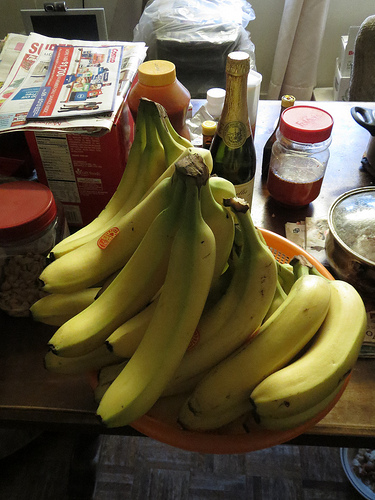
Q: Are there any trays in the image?
A: No, there are no trays.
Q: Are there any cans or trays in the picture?
A: No, there are no trays or cans.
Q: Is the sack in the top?
A: Yes, the sack is in the top of the image.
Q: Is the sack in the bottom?
A: No, the sack is in the top of the image.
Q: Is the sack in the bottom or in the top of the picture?
A: The sack is in the top of the image.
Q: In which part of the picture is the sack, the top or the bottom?
A: The sack is in the top of the image.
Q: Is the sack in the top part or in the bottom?
A: The sack is in the top of the image.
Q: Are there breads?
A: No, there are no breads.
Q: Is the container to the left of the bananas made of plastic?
A: Yes, the container is made of plastic.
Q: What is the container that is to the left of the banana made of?
A: The container is made of plastic.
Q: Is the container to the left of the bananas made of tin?
A: No, the container is made of plastic.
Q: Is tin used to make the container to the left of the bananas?
A: No, the container is made of plastic.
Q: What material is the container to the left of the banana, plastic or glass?
A: The container is made of plastic.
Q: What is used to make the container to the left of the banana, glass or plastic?
A: The container is made of plastic.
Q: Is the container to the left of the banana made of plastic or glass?
A: The container is made of plastic.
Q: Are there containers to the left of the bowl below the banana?
A: Yes, there is a container to the left of the bowl.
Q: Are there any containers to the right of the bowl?
A: No, the container is to the left of the bowl.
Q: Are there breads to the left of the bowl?
A: No, there is a container to the left of the bowl.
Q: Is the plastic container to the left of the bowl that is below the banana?
A: Yes, the container is to the left of the bowl.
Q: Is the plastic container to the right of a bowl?
A: No, the container is to the left of a bowl.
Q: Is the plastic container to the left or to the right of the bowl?
A: The container is to the left of the bowl.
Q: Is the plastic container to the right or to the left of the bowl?
A: The container is to the left of the bowl.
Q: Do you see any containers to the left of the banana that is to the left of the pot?
A: Yes, there is a container to the left of the banana.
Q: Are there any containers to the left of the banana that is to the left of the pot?
A: Yes, there is a container to the left of the banana.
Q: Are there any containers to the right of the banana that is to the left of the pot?
A: No, the container is to the left of the banana.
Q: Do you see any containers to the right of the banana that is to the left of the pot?
A: No, the container is to the left of the banana.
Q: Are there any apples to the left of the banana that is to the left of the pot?
A: No, there is a container to the left of the banana.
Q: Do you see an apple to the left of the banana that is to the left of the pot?
A: No, there is a container to the left of the banana.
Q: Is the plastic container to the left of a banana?
A: Yes, the container is to the left of a banana.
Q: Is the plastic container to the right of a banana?
A: No, the container is to the left of a banana.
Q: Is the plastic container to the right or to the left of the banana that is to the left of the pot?
A: The container is to the left of the banana.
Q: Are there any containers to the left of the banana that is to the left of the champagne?
A: Yes, there is a container to the left of the banana.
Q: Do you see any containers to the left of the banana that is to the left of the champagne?
A: Yes, there is a container to the left of the banana.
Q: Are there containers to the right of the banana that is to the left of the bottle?
A: No, the container is to the left of the banana.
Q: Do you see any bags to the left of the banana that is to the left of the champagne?
A: No, there is a container to the left of the banana.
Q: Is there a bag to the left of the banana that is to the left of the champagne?
A: No, there is a container to the left of the banana.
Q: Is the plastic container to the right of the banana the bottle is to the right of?
A: No, the container is to the left of the banana.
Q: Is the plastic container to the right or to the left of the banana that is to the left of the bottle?
A: The container is to the left of the banana.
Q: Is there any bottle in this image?
A: Yes, there is a bottle.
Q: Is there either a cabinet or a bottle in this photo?
A: Yes, there is a bottle.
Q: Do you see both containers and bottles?
A: Yes, there are both a bottle and a container.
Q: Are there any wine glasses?
A: No, there are no wine glasses.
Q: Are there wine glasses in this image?
A: No, there are no wine glasses.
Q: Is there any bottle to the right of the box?
A: Yes, there is a bottle to the right of the box.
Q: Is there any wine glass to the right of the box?
A: No, there is a bottle to the right of the box.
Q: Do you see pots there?
A: Yes, there is a pot.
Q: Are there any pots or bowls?
A: Yes, there is a pot.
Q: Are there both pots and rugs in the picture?
A: No, there is a pot but no rugs.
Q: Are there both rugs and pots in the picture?
A: No, there is a pot but no rugs.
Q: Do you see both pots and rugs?
A: No, there is a pot but no rugs.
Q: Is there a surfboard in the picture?
A: No, there are no surfboards.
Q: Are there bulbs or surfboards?
A: No, there are no surfboards or bulbs.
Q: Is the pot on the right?
A: Yes, the pot is on the right of the image.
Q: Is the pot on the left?
A: No, the pot is on the right of the image.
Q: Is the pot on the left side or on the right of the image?
A: The pot is on the right of the image.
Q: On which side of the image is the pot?
A: The pot is on the right of the image.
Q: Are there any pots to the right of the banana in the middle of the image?
A: Yes, there is a pot to the right of the banana.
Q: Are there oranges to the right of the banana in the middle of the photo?
A: No, there is a pot to the right of the banana.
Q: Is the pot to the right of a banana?
A: Yes, the pot is to the right of a banana.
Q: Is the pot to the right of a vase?
A: No, the pot is to the right of a banana.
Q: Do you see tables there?
A: Yes, there is a table.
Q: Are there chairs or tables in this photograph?
A: Yes, there is a table.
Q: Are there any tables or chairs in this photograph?
A: Yes, there is a table.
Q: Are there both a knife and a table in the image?
A: No, there is a table but no knives.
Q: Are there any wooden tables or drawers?
A: Yes, there is a wood table.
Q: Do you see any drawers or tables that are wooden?
A: Yes, the table is wooden.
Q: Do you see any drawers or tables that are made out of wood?
A: Yes, the table is made of wood.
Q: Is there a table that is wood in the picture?
A: Yes, there is a wood table.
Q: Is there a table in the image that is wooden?
A: Yes, there is a table that is wooden.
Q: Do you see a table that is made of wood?
A: Yes, there is a table that is made of wood.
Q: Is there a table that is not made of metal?
A: Yes, there is a table that is made of wood.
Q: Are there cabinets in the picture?
A: No, there are no cabinets.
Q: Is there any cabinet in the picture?
A: No, there are no cabinets.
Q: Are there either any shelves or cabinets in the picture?
A: No, there are no cabinets or shelves.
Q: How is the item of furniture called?
A: The piece of furniture is a table.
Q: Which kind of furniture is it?
A: The piece of furniture is a table.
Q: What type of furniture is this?
A: This is a table.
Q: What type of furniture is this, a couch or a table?
A: This is a table.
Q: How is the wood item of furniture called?
A: The piece of furniture is a table.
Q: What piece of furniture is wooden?
A: The piece of furniture is a table.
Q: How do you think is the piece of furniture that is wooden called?
A: The piece of furniture is a table.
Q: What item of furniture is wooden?
A: The piece of furniture is a table.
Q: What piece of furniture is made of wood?
A: The piece of furniture is a table.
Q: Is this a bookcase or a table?
A: This is a table.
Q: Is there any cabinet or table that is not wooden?
A: No, there is a table but it is wooden.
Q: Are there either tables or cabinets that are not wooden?
A: No, there is a table but it is wooden.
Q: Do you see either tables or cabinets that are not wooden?
A: No, there is a table but it is wooden.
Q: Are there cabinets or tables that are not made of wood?
A: No, there is a table but it is made of wood.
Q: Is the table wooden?
A: Yes, the table is wooden.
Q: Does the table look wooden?
A: Yes, the table is wooden.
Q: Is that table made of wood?
A: Yes, the table is made of wood.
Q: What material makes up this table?
A: The table is made of wood.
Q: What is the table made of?
A: The table is made of wood.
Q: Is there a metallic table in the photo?
A: No, there is a table but it is wooden.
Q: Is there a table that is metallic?
A: No, there is a table but it is wooden.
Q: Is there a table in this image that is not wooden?
A: No, there is a table but it is wooden.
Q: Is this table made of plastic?
A: No, the table is made of wood.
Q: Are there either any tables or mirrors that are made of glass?
A: No, there is a table but it is made of wood.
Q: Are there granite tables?
A: No, there is a table but it is made of wood.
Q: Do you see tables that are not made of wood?
A: No, there is a table but it is made of wood.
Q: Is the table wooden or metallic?
A: The table is wooden.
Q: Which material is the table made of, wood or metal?
A: The table is made of wood.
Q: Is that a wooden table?
A: Yes, that is a wooden table.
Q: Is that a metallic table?
A: No, that is a wooden table.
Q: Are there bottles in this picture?
A: Yes, there is a bottle.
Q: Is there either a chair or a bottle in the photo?
A: Yes, there is a bottle.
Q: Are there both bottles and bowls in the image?
A: Yes, there are both a bottle and a bowl.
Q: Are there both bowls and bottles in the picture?
A: Yes, there are both a bottle and a bowl.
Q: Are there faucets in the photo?
A: No, there are no faucets.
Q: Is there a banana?
A: Yes, there is a banana.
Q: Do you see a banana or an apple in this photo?
A: Yes, there is a banana.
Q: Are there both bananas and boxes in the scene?
A: Yes, there are both a banana and a box.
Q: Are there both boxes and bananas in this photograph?
A: Yes, there are both a banana and a box.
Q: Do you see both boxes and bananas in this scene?
A: Yes, there are both a banana and a box.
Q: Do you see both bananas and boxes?
A: Yes, there are both a banana and a box.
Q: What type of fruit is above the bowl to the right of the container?
A: The fruit is a banana.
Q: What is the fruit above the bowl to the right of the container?
A: The fruit is a banana.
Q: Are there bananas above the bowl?
A: Yes, there is a banana above the bowl.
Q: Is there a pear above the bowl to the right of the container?
A: No, there is a banana above the bowl.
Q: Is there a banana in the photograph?
A: Yes, there are bananas.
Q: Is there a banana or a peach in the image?
A: Yes, there are bananas.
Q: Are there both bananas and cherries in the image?
A: No, there are bananas but no cherries.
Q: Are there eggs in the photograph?
A: No, there are no eggs.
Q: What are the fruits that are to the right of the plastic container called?
A: The fruits are bananas.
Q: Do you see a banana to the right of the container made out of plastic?
A: Yes, there are bananas to the right of the container.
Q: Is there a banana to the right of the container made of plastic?
A: Yes, there are bananas to the right of the container.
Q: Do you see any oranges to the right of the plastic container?
A: No, there are bananas to the right of the container.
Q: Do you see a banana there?
A: Yes, there is a banana.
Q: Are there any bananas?
A: Yes, there is a banana.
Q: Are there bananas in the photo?
A: Yes, there is a banana.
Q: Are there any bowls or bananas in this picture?
A: Yes, there is a banana.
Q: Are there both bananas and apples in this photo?
A: No, there is a banana but no apples.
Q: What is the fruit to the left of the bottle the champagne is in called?
A: The fruit is a banana.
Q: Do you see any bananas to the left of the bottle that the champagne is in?
A: Yes, there is a banana to the left of the bottle.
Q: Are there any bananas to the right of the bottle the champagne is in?
A: No, the banana is to the left of the bottle.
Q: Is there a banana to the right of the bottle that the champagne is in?
A: No, the banana is to the left of the bottle.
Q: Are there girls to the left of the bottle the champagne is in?
A: No, there is a banana to the left of the bottle.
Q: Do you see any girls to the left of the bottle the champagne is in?
A: No, there is a banana to the left of the bottle.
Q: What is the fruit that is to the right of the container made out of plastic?
A: The fruit is a banana.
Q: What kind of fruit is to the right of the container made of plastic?
A: The fruit is a banana.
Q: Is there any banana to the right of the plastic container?
A: Yes, there is a banana to the right of the container.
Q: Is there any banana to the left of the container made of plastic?
A: No, the banana is to the right of the container.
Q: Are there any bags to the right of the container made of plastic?
A: No, there is a banana to the right of the container.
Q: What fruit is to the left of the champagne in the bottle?
A: The fruit is a banana.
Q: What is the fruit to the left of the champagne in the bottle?
A: The fruit is a banana.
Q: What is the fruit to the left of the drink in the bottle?
A: The fruit is a banana.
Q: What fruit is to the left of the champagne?
A: The fruit is a banana.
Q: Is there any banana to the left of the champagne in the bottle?
A: Yes, there is a banana to the left of the champagne.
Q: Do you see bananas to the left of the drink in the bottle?
A: Yes, there is a banana to the left of the champagne.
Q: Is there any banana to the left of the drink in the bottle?
A: Yes, there is a banana to the left of the champagne.